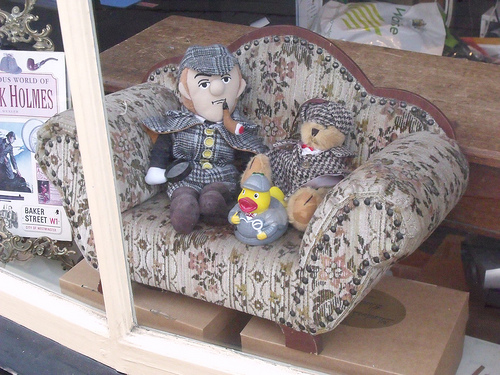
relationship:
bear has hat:
[237, 97, 361, 234] [287, 98, 357, 159]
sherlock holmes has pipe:
[138, 41, 268, 234] [221, 99, 245, 139]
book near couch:
[0, 50, 74, 243] [34, 23, 473, 358]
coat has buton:
[142, 105, 266, 186] [202, 126, 217, 137]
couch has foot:
[34, 23, 473, 358] [279, 324, 326, 357]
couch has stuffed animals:
[34, 23, 473, 358] [136, 44, 356, 246]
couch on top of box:
[34, 23, 473, 358] [238, 275, 474, 374]